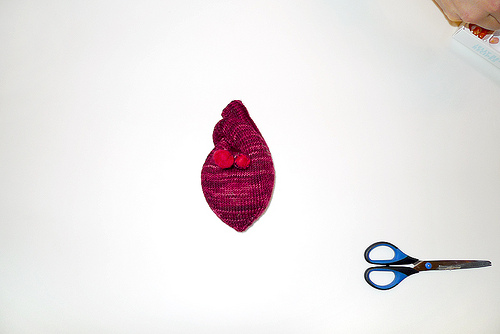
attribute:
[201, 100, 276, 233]
cloth — purple, laying down, knitted, focused, red, hat, burgandy, pink, plaid patterned, light pink, striped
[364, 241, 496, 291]
scissors — blue, black, plastic, metal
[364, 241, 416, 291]
handle — blue, black, brown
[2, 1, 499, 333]
table — white, really white, background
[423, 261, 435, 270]
screw — blue, small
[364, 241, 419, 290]
outline — black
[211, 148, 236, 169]
ball — pink, small, decorative, red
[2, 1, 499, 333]
photo — mostly empty